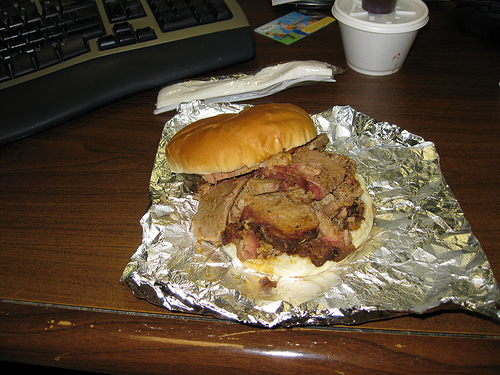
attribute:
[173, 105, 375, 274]
sandwhich — bbq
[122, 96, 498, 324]
foil — silver, gre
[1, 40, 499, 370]
table — wooden, brown, brow, red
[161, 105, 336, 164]
bun — brown, brow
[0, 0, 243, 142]
keyboard — black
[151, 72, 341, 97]
napkin — white